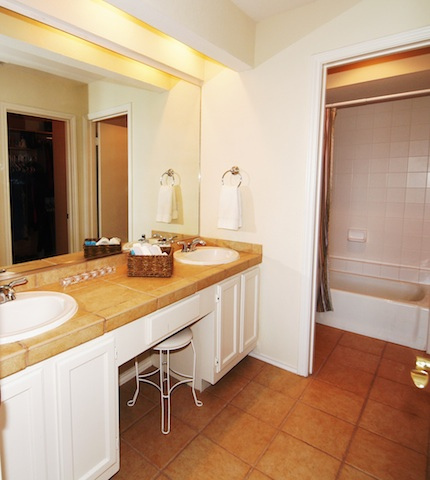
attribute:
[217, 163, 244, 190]
ring — silver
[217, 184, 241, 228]
hand towel — white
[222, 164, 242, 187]
rack — silver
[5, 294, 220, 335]
sink — white, porcelain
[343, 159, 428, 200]
reflection — hanging 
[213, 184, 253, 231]
towel — white 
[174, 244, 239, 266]
sink — white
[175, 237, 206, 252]
faucet — silver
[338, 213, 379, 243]
soap holder — white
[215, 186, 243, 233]
hand towel — white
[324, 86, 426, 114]
rod — white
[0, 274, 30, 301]
faucet — chrome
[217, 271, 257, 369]
cabinets — white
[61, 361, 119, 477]
cabinets — white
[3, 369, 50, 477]
cabinets — white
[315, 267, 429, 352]
bath tub — porcelain, white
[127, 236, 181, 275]
basket — brown, wicker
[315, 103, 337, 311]
curtain — brown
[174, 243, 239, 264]
sink basin — white , porcelain 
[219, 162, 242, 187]
holder — silver, round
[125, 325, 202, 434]
stool — small, white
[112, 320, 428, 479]
floor — tiled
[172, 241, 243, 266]
sink — white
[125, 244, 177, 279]
basket — square, brown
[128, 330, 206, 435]
stool — white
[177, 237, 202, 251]
faucet — chrome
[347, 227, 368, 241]
soap holder — white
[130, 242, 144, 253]
product — bathroom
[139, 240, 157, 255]
product — bathroom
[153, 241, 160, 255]
product — bathroom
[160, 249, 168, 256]
product — bathroom